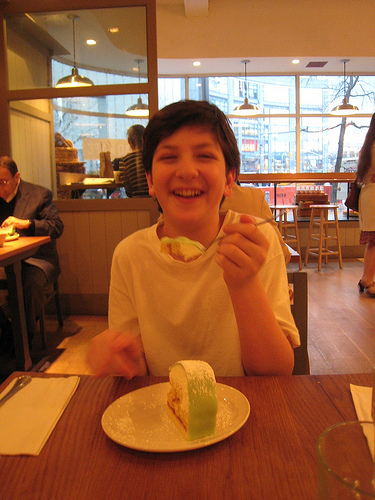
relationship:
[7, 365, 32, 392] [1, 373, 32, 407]
handle of utensil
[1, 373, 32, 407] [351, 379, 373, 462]
utensil on napkin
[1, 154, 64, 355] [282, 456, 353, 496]
man standinsitting at table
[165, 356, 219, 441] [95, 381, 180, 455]
cake with sugar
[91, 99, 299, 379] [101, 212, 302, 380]
boy wearing shirt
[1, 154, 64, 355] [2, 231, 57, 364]
man sitting at restaurant table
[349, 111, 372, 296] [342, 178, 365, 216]
woman with purse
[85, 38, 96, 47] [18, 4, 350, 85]
light on ceiling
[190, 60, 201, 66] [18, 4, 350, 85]
light on ceiling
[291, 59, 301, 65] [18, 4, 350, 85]
light on ceiling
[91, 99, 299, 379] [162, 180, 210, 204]
boy with smile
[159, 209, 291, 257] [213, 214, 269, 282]
fork in hand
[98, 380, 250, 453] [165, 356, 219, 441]
plate with cake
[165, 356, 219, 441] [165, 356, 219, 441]
cake with cake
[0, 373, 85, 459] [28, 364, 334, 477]
napkin on table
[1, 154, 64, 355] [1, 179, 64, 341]
man in suit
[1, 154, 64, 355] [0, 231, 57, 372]
man sitting at restaurant table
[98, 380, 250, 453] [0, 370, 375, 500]
plate on table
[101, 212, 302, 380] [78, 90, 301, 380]
shirt of boy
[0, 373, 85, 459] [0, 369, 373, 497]
napkin on table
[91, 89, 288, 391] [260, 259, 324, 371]
boy sitting on chair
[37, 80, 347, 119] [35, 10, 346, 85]
lights hanging from ceiling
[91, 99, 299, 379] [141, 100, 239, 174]
boy has hair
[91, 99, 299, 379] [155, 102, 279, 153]
boy has hair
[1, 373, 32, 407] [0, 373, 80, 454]
utensil on top of napkin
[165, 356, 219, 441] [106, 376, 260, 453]
cake on top of plate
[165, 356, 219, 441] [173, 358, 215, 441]
cake has top coat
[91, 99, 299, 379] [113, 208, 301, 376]
boy wearing shirt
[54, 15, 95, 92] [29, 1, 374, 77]
light hanging from ceiling